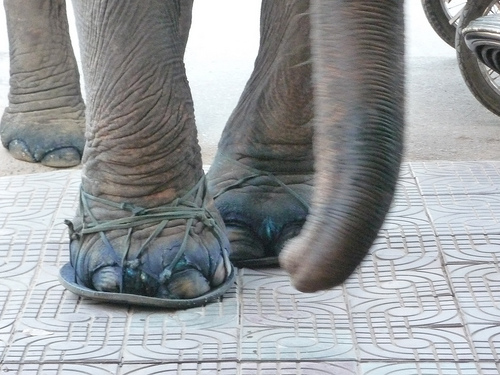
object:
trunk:
[277, 2, 407, 295]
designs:
[0, 159, 497, 374]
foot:
[207, 171, 314, 266]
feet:
[0, 96, 88, 168]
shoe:
[58, 256, 234, 308]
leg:
[68, 1, 215, 223]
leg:
[0, 0, 84, 121]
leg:
[204, 1, 318, 196]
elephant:
[1, 0, 404, 310]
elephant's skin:
[70, 0, 199, 203]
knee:
[85, 74, 200, 156]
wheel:
[453, 21, 500, 115]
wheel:
[419, 0, 459, 39]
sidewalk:
[0, 155, 499, 375]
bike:
[417, 1, 500, 118]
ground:
[304, 293, 497, 374]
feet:
[58, 204, 237, 308]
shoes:
[56, 191, 236, 309]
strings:
[58, 192, 230, 294]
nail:
[168, 275, 210, 298]